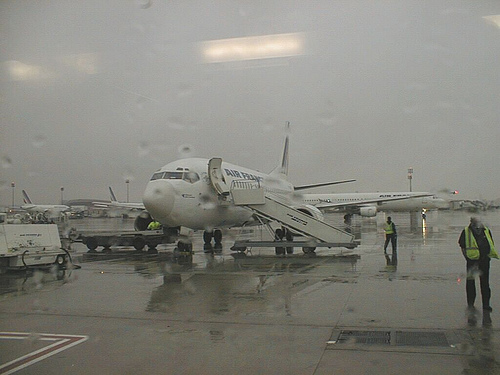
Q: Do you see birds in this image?
A: No, there are no birds.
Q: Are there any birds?
A: No, there are no birds.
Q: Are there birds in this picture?
A: No, there are no birds.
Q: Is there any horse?
A: No, there are no horses.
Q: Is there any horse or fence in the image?
A: No, there are no horses or fences.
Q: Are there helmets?
A: No, there are no helmets.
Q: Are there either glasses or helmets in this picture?
A: No, there are no helmets or glasses.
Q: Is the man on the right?
A: Yes, the man is on the right of the image.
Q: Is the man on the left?
A: No, the man is on the right of the image.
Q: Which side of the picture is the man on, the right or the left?
A: The man is on the right of the image.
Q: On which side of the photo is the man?
A: The man is on the right of the image.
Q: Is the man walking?
A: Yes, the man is walking.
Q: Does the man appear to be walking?
A: Yes, the man is walking.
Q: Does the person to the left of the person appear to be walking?
A: Yes, the man is walking.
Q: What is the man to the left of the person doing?
A: The man is walking.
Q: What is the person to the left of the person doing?
A: The man is walking.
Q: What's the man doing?
A: The man is walking.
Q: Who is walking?
A: The man is walking.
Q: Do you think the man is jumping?
A: No, the man is walking.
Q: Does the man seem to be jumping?
A: No, the man is walking.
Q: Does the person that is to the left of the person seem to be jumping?
A: No, the man is walking.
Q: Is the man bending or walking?
A: The man is walking.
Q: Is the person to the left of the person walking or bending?
A: The man is walking.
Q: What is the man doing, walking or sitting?
A: The man is walking.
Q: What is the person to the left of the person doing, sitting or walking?
A: The man is walking.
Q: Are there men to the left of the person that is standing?
A: Yes, there is a man to the left of the person.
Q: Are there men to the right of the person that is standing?
A: No, the man is to the left of the person.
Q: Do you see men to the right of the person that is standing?
A: No, the man is to the left of the person.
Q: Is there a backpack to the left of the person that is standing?
A: No, there is a man to the left of the person.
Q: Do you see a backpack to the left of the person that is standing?
A: No, there is a man to the left of the person.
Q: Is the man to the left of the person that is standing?
A: Yes, the man is to the left of the person.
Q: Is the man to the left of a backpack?
A: No, the man is to the left of the person.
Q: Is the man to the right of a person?
A: No, the man is to the left of a person.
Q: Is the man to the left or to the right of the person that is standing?
A: The man is to the left of the person.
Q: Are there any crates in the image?
A: No, there are no crates.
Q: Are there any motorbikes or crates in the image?
A: No, there are no crates or motorbikes.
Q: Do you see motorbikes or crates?
A: No, there are no crates or motorbikes.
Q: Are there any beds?
A: Yes, there is a bed.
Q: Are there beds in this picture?
A: Yes, there is a bed.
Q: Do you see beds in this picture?
A: Yes, there is a bed.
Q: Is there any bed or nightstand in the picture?
A: Yes, there is a bed.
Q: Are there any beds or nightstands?
A: Yes, there is a bed.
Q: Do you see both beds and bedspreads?
A: No, there is a bed but no bedspreads.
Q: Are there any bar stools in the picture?
A: No, there are no bar stools.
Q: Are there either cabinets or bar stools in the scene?
A: No, there are no bar stools or cabinets.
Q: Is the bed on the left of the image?
A: Yes, the bed is on the left of the image.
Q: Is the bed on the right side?
A: No, the bed is on the left of the image.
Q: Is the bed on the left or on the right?
A: The bed is on the left of the image.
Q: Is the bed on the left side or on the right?
A: The bed is on the left of the image.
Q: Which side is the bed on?
A: The bed is on the left of the image.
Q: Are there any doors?
A: Yes, there is a door.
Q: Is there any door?
A: Yes, there is a door.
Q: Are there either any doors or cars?
A: Yes, there is a door.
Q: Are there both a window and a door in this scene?
A: Yes, there are both a door and a window.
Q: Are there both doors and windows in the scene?
A: Yes, there are both a door and a window.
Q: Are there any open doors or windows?
A: Yes, there is an open door.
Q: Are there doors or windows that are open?
A: Yes, the door is open.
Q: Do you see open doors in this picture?
A: Yes, there is an open door.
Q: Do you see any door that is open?
A: Yes, there is a door that is open.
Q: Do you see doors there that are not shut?
A: Yes, there is a open door.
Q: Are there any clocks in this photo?
A: No, there are no clocks.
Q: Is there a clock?
A: No, there are no clocks.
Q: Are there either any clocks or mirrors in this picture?
A: No, there are no clocks or mirrors.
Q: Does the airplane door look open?
A: Yes, the door is open.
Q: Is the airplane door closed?
A: No, the door is open.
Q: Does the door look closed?
A: No, the door is open.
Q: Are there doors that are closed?
A: No, there is a door but it is open.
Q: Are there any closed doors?
A: No, there is a door but it is open.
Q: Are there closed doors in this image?
A: No, there is a door but it is open.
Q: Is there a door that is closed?
A: No, there is a door but it is open.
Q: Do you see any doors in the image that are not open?
A: No, there is a door but it is open.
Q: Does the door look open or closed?
A: The door is open.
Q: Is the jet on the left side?
A: Yes, the jet is on the left of the image.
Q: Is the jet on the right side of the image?
A: No, the jet is on the left of the image.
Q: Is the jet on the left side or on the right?
A: The jet is on the left of the image.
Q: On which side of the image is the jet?
A: The jet is on the left of the image.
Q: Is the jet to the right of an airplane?
A: No, the jet is to the left of an airplane.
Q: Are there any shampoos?
A: No, there are no shampoos.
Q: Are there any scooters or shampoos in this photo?
A: No, there are no shampoos or scooters.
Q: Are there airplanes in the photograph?
A: Yes, there is an airplane.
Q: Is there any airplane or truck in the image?
A: Yes, there is an airplane.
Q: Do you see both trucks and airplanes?
A: No, there is an airplane but no trucks.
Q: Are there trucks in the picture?
A: No, there are no trucks.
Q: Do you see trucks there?
A: No, there are no trucks.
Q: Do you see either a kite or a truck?
A: No, there are no trucks or kites.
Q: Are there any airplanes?
A: Yes, there is an airplane.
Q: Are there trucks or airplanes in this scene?
A: Yes, there is an airplane.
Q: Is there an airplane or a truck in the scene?
A: Yes, there is an airplane.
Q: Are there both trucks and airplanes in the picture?
A: No, there is an airplane but no trucks.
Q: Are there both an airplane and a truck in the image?
A: No, there is an airplane but no trucks.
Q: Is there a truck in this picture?
A: No, there are no trucks.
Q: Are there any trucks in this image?
A: No, there are no trucks.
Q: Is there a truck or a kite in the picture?
A: No, there are no trucks or kites.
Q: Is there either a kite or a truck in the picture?
A: No, there are no trucks or kites.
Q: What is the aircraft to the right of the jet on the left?
A: The aircraft is an airplane.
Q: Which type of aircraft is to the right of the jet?
A: The aircraft is an airplane.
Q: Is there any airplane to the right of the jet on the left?
A: Yes, there is an airplane to the right of the jet.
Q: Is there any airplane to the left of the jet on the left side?
A: No, the airplane is to the right of the jet.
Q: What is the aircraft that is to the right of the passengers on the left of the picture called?
A: The aircraft is an airplane.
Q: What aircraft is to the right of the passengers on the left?
A: The aircraft is an airplane.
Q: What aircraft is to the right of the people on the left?
A: The aircraft is an airplane.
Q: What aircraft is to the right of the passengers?
A: The aircraft is an airplane.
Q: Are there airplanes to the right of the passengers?
A: Yes, there is an airplane to the right of the passengers.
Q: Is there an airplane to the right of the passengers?
A: Yes, there is an airplane to the right of the passengers.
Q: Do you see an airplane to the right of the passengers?
A: Yes, there is an airplane to the right of the passengers.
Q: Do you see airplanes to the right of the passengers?
A: Yes, there is an airplane to the right of the passengers.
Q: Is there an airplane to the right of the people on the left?
A: Yes, there is an airplane to the right of the passengers.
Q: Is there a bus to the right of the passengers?
A: No, there is an airplane to the right of the passengers.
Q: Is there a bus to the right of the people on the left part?
A: No, there is an airplane to the right of the passengers.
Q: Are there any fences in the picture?
A: No, there are no fences.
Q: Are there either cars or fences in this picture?
A: No, there are no fences or cars.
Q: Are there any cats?
A: No, there are no cats.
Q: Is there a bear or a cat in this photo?
A: No, there are no cats or bears.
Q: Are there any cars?
A: No, there are no cars.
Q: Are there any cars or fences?
A: No, there are no cars or fences.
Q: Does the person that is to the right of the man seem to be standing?
A: Yes, the person is standing.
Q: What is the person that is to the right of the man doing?
A: The person is standing.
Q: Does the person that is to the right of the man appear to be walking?
A: No, the person is standing.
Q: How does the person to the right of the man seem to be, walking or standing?
A: The person is standing.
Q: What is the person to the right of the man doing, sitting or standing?
A: The person is standing.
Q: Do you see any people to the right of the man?
A: Yes, there is a person to the right of the man.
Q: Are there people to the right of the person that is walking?
A: Yes, there is a person to the right of the man.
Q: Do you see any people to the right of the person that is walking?
A: Yes, there is a person to the right of the man.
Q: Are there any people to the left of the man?
A: No, the person is to the right of the man.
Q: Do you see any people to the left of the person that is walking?
A: No, the person is to the right of the man.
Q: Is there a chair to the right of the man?
A: No, there is a person to the right of the man.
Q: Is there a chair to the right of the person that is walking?
A: No, there is a person to the right of the man.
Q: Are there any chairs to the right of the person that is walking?
A: No, there is a person to the right of the man.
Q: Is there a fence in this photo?
A: No, there are no fences.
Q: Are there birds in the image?
A: No, there are no birds.